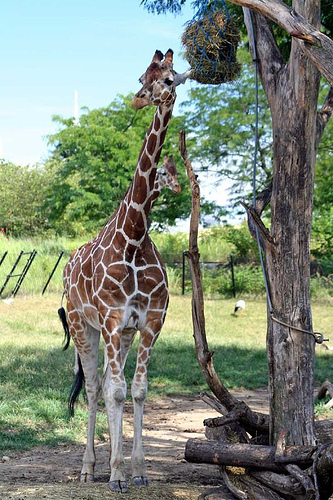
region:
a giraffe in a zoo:
[15, 14, 240, 496]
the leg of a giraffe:
[80, 345, 101, 485]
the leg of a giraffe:
[99, 327, 129, 494]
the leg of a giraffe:
[132, 332, 154, 491]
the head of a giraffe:
[125, 48, 197, 113]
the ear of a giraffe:
[172, 67, 196, 91]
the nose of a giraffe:
[122, 85, 148, 111]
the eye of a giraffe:
[161, 76, 173, 90]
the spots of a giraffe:
[78, 256, 155, 314]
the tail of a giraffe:
[63, 337, 84, 418]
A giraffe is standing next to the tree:
[57, 41, 191, 376]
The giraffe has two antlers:
[128, 48, 194, 108]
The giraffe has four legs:
[58, 303, 165, 496]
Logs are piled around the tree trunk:
[179, 345, 323, 496]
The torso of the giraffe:
[53, 224, 183, 351]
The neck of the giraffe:
[116, 100, 163, 245]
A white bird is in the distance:
[229, 292, 247, 317]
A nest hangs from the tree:
[185, 10, 245, 91]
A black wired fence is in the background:
[5, 244, 329, 306]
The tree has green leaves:
[55, 104, 204, 234]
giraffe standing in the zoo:
[73, 37, 173, 481]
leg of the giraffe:
[67, 349, 164, 498]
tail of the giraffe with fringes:
[55, 295, 82, 406]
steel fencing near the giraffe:
[4, 256, 57, 291]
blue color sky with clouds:
[28, 21, 108, 108]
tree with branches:
[69, 108, 206, 234]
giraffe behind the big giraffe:
[154, 152, 179, 205]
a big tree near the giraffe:
[262, 51, 313, 411]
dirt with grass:
[12, 388, 66, 494]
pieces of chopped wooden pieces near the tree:
[205, 382, 331, 499]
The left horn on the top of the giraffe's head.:
[155, 49, 163, 62]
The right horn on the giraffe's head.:
[164, 48, 173, 63]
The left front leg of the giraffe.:
[105, 325, 128, 490]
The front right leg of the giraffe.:
[134, 331, 151, 485]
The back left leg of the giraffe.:
[78, 331, 100, 483]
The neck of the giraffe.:
[109, 103, 176, 243]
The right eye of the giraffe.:
[164, 76, 173, 87]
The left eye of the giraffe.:
[139, 74, 143, 83]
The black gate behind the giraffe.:
[2, 242, 246, 304]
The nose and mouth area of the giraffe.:
[131, 92, 149, 109]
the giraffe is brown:
[62, 126, 187, 383]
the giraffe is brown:
[58, 233, 191, 352]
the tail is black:
[52, 330, 99, 427]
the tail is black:
[38, 302, 86, 418]